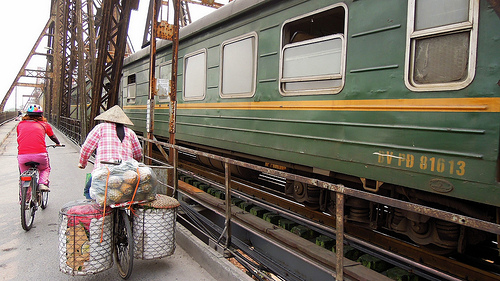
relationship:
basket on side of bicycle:
[58, 199, 116, 279] [84, 158, 154, 279]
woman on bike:
[10, 91, 62, 196] [7, 170, 54, 230]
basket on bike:
[58, 202, 116, 273] [114, 187, 135, 274]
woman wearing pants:
[15, 102, 61, 205] [17, 151, 54, 199]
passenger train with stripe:
[114, 0, 496, 277] [121, 100, 497, 118]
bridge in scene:
[4, 1, 171, 124] [4, 8, 498, 278]